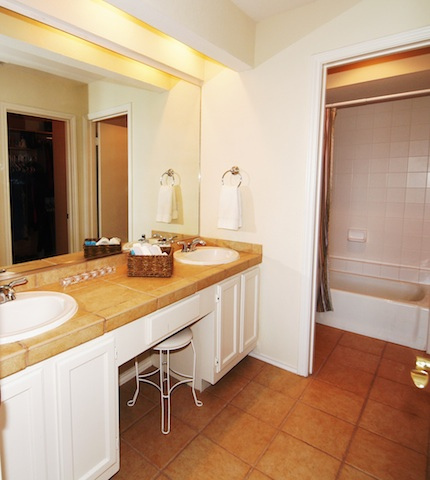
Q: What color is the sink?
A: White.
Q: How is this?
A: Clear.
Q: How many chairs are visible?
A: One.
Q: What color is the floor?
A: Brown.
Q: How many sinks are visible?
A: Two.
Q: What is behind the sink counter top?
A: A mirror.